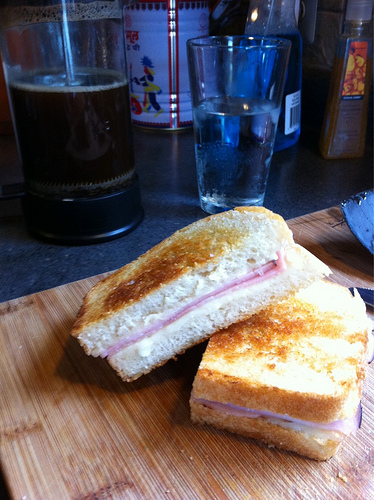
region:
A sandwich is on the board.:
[0, 206, 371, 498]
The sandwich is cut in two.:
[71, 205, 365, 458]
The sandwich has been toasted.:
[176, 232, 226, 264]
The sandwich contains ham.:
[248, 262, 280, 283]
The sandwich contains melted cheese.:
[136, 336, 157, 358]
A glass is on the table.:
[187, 34, 292, 204]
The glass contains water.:
[195, 97, 278, 204]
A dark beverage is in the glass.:
[5, 73, 132, 186]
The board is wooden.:
[40, 416, 152, 498]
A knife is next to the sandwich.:
[366, 286, 372, 305]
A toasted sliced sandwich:
[62, 192, 370, 467]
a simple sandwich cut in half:
[39, 200, 351, 459]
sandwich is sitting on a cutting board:
[0, 203, 366, 493]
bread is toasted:
[62, 205, 344, 464]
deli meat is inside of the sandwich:
[90, 250, 284, 359]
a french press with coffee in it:
[2, 0, 145, 244]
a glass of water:
[185, 25, 282, 210]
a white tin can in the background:
[113, 0, 205, 132]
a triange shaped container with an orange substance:
[319, 0, 369, 168]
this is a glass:
[183, 27, 279, 194]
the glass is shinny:
[221, 122, 262, 178]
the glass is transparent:
[226, 63, 268, 116]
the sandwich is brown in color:
[248, 364, 287, 394]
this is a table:
[77, 432, 215, 495]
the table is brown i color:
[89, 390, 168, 477]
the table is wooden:
[47, 369, 111, 433]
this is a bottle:
[326, 19, 366, 160]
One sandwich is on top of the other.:
[67, 201, 369, 462]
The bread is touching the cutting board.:
[56, 269, 158, 395]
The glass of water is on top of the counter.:
[175, 30, 301, 235]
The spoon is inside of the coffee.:
[49, 0, 116, 162]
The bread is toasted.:
[107, 263, 150, 317]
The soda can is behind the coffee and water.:
[95, 0, 251, 157]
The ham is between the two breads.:
[138, 300, 221, 328]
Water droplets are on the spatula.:
[337, 184, 372, 219]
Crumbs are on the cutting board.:
[160, 441, 214, 496]